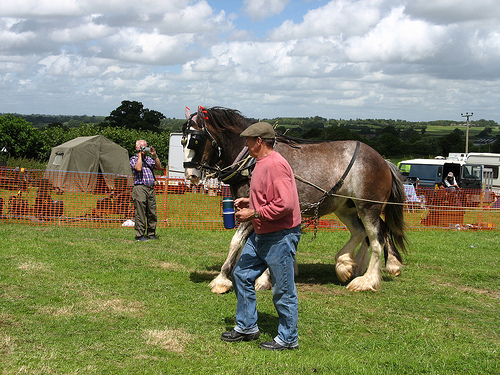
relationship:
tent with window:
[40, 134, 135, 197] [52, 149, 66, 168]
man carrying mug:
[219, 120, 304, 353] [221, 196, 236, 215]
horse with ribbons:
[179, 102, 410, 294] [198, 104, 210, 123]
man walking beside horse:
[219, 120, 304, 353] [179, 102, 410, 294]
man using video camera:
[128, 136, 166, 242] [139, 144, 155, 158]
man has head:
[443, 171, 461, 194] [445, 169, 457, 184]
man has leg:
[219, 120, 304, 353] [230, 243, 270, 335]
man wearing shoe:
[219, 120, 304, 353] [221, 328, 261, 342]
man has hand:
[219, 120, 304, 353] [234, 195, 254, 212]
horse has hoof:
[179, 102, 410, 294] [337, 264, 355, 283]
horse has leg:
[179, 102, 410, 294] [345, 202, 388, 296]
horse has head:
[179, 102, 410, 294] [181, 104, 225, 181]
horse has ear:
[179, 102, 410, 294] [194, 104, 212, 131]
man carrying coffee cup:
[219, 120, 304, 353] [221, 209, 239, 230]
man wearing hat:
[219, 120, 304, 353] [238, 119, 278, 142]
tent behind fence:
[40, 134, 135, 197] [0, 165, 499, 234]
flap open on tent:
[100, 155, 118, 195] [40, 134, 135, 197]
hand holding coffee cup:
[234, 195, 254, 212] [221, 196, 236, 215]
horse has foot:
[179, 102, 410, 294] [205, 273, 233, 297]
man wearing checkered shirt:
[128, 136, 166, 242] [130, 153, 156, 189]